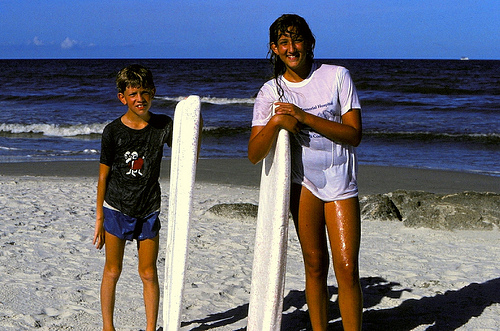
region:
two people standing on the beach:
[68, 5, 376, 330]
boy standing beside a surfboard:
[85, 63, 205, 328]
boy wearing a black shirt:
[90, 72, 165, 212]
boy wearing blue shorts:
[91, 202, 159, 242]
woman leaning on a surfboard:
[240, 5, 391, 330]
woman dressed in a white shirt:
[241, 5, 363, 205]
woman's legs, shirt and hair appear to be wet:
[251, 5, 367, 269]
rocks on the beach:
[202, 178, 497, 249]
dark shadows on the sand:
[180, 250, 495, 325]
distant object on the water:
[415, 45, 490, 90]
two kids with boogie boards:
[63, 10, 495, 247]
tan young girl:
[224, 17, 396, 328]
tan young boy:
[70, 40, 200, 293]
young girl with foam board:
[232, 11, 419, 328]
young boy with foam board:
[65, 47, 217, 328]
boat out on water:
[430, 41, 475, 108]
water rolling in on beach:
[10, 35, 77, 257]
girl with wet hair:
[241, 4, 350, 137]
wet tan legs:
[321, 205, 381, 325]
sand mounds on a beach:
[376, 137, 488, 250]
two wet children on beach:
[92, 7, 372, 329]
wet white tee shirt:
[263, 56, 362, 210]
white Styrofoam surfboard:
[142, 89, 207, 329]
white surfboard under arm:
[247, 122, 292, 305]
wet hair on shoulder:
[263, 58, 284, 100]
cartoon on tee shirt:
[117, 142, 152, 184]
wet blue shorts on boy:
[95, 197, 167, 247]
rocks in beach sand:
[400, 194, 489, 242]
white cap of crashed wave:
[31, 117, 104, 139]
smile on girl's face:
[277, 52, 303, 64]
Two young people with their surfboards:
[75, 8, 422, 325]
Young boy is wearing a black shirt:
[77, 110, 183, 220]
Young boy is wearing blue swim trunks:
[88, 194, 173, 261]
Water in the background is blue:
[3, 58, 493, 146]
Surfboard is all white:
[163, 89, 208, 329]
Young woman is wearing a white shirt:
[241, 71, 397, 219]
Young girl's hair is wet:
[256, 1, 342, 103]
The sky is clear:
[5, 3, 497, 55]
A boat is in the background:
[447, 53, 481, 70]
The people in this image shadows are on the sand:
[169, 257, 493, 329]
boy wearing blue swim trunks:
[91, 62, 175, 329]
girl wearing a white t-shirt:
[244, 12, 363, 329]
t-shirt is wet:
[246, 63, 362, 203]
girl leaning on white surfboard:
[248, 122, 292, 329]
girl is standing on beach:
[245, 10, 364, 330]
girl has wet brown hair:
[266, 14, 316, 101]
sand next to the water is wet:
[5, 155, 498, 207]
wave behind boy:
[1, 118, 106, 138]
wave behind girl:
[159, 91, 260, 108]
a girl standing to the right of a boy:
[91, 12, 364, 329]